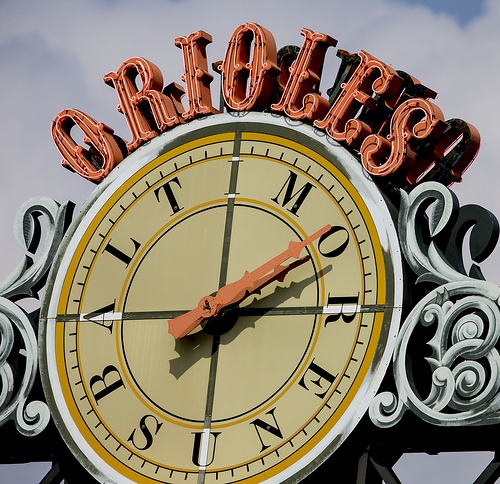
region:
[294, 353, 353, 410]
a letter on a clock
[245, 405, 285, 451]
a letter on a clock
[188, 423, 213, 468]
a letter on a clock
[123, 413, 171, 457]
a letter on a clock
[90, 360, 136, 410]
a letter on a clock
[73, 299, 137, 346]
a letter on a clock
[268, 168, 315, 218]
black letter on clock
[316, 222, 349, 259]
black letter on clock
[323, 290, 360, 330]
black letter on clock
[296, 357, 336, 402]
black letter on clock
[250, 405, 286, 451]
black letter on clock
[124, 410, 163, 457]
black letter on clock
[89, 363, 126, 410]
black letter on clock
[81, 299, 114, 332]
black letter on clock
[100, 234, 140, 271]
black letter on clock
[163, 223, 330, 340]
Orange hands on a clock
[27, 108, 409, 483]
A round clock face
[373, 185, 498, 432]
Filigree design near a clock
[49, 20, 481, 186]
Orange letters on top of a clock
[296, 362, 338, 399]
Black letter E on a clock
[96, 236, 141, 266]
Black letter L on a clock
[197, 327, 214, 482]
Divider line on the face of a clock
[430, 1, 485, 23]
Blue patch of sky through the clouds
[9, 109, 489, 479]
clock with name of local newspaper in black letters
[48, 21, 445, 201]
name of local baseball team in red neon letters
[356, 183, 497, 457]
curlicue decorations on side of clock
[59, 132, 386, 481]
red clock hands on tan face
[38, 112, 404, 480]
black and white rim around clock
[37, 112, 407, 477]
black lines dividing clock into four sections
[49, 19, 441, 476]
letters written in capital letters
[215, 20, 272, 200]
Letter "O" on top of letter "I"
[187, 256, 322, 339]
the hand on the clock is red.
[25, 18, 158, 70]
The sky is cloudy.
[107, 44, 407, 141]
Red letter above the clock.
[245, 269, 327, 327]
The reflection of the hand on clock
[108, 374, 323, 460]
Black letters on face of the clock.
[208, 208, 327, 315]
The time is 2:10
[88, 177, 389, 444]
the clock is yellow and white.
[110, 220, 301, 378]
The face of the clock is pale yellow.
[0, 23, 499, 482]
large ornate clock celebrates sports team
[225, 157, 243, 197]
letter I is at 12:00 position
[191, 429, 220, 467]
letter U is at 6:00 position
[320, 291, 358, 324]
letter R is at 3:00 position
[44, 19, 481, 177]
An orange sign atop a clock face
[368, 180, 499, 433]
A white decoration on the side of a clock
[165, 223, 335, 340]
An orange clock needle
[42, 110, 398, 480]
A large clock face with decoration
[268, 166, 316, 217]
The letter M on a clock face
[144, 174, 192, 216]
The letter T on a clock face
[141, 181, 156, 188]
Marks on a clock to indicate seconds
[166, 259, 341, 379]
The shadow of a clock face needle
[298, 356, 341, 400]
The letter E on the front of a clock face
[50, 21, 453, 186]
An orange sign that reads Orioles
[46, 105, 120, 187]
Letter of a sign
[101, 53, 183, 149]
Letter of a sign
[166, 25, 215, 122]
Letter of a sign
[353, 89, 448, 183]
Letter of a sign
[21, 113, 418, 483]
A round and large clock face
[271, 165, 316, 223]
Letter on a clock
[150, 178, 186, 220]
Letter on a clock